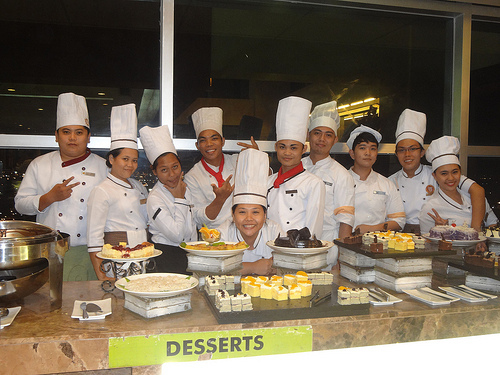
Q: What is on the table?
A: Desserts.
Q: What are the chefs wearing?
A: Chef hats.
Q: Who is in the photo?
A: Chefs.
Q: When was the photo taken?
A: Night.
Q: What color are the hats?
A: White.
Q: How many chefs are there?
A: Ten.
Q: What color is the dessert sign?
A: Green.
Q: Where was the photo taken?
A: At a bakery stand.